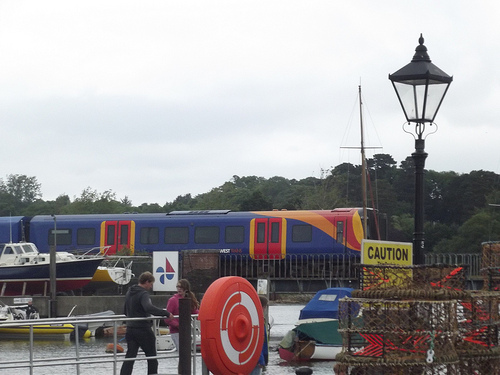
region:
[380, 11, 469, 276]
black lamp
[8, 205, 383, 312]
blue train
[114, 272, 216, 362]
people walking along dock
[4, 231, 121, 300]
boat parked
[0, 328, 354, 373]
lake of water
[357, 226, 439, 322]
yellow caution sign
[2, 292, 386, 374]
boats in the water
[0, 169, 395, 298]
this is a train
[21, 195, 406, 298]
the train is blue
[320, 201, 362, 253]
red trim on train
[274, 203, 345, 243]
orange trim on train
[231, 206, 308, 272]
red doors on train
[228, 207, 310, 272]
double doors on trains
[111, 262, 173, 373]
this is a man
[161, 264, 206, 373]
this is a woman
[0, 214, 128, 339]
this is a boat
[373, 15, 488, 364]
a light on a post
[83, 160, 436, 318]
a train on tracks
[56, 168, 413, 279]
a train is blue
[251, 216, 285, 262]
a door on a train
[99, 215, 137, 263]
a door on a train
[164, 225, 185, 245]
window on a train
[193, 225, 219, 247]
window on a train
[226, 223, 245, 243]
window on a train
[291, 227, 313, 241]
window on a train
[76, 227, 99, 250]
window on a train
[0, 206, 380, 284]
Blue, red and yellow train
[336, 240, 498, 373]
Brown weaved rope containers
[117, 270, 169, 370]
Man wearing dark gray long-sleeve hoodie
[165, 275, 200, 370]
Woman wearing pink sweater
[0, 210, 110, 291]
Red, white and blue boat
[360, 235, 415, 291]
Yellow caution sign with black letters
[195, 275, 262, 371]
Round orange and white object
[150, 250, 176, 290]
Sign with a red, blue and white design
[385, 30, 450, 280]
Tall black street light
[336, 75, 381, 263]
Tall spar of a sailboat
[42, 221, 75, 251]
black window on train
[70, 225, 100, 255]
black window on train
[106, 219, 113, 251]
black window on train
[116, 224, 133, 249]
black window on train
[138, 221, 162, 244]
black window on train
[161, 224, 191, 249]
black window on train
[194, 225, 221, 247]
black window on train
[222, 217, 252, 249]
black window on train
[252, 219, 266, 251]
black window on train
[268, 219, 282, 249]
black window on train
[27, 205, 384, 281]
a blue red and orange train car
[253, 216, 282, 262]
a pair of red train doors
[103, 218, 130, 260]
a pair of red train doors